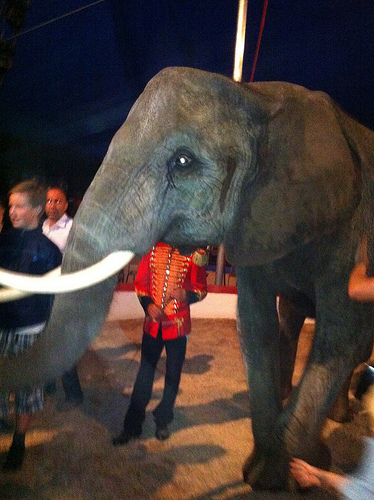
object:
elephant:
[8, 64, 373, 495]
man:
[119, 229, 212, 446]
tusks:
[3, 232, 130, 298]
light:
[180, 158, 185, 163]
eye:
[171, 147, 202, 173]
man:
[45, 177, 88, 407]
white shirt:
[41, 218, 77, 254]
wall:
[6, 69, 88, 247]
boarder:
[19, 39, 99, 129]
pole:
[223, 2, 253, 86]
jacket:
[3, 234, 65, 330]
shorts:
[11, 325, 57, 416]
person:
[348, 251, 374, 302]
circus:
[60, 59, 119, 128]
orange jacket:
[149, 243, 190, 324]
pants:
[128, 332, 167, 430]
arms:
[189, 256, 205, 289]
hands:
[147, 302, 166, 320]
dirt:
[87, 436, 220, 492]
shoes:
[115, 418, 144, 443]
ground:
[74, 311, 286, 498]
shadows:
[100, 369, 124, 431]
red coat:
[131, 243, 210, 339]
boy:
[2, 177, 67, 475]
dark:
[11, 137, 85, 171]